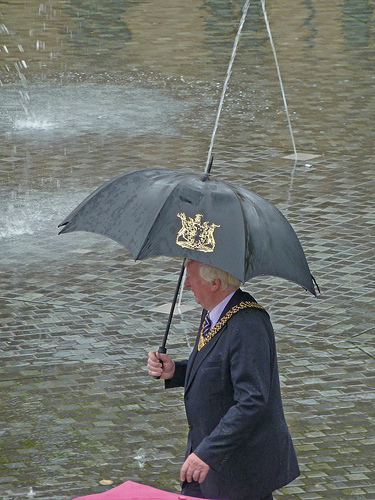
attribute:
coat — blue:
[154, 284, 318, 490]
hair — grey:
[180, 255, 244, 295]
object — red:
[72, 479, 205, 498]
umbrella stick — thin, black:
[158, 263, 188, 348]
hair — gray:
[201, 265, 216, 274]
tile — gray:
[282, 147, 321, 164]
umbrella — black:
[43, 162, 332, 316]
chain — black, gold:
[190, 307, 260, 349]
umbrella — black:
[57, 166, 316, 297]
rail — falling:
[2, 18, 44, 116]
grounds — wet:
[25, 47, 187, 154]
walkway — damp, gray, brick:
[1, 3, 373, 498]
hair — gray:
[182, 256, 239, 292]